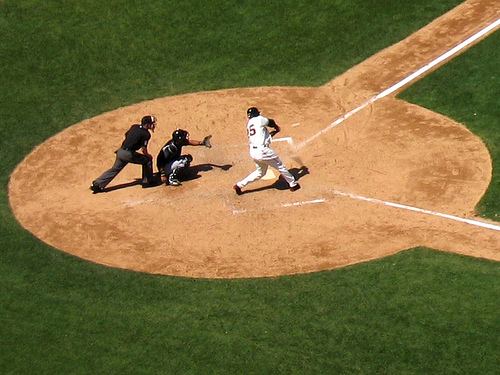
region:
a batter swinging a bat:
[233, 104, 308, 192]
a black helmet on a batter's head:
[243, 105, 260, 116]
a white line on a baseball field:
[337, 186, 498, 233]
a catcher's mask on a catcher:
[176, 127, 191, 145]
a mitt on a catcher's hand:
[203, 131, 214, 152]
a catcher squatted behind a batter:
[156, 126, 213, 187]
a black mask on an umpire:
[144, 112, 159, 129]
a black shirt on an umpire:
[120, 123, 155, 149]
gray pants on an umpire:
[93, 149, 154, 189]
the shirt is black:
[104, 119, 154, 155]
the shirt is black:
[114, 122, 147, 158]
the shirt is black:
[117, 115, 158, 159]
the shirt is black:
[111, 120, 146, 150]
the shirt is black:
[110, 121, 161, 168]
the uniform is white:
[225, 107, 304, 213]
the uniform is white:
[228, 121, 285, 203]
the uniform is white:
[230, 115, 298, 195]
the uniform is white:
[241, 107, 284, 204]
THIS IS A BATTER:
[218, 92, 309, 198]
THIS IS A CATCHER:
[155, 120, 216, 188]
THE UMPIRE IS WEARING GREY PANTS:
[68, 110, 168, 200]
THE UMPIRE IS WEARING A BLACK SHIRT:
[70, 107, 161, 195]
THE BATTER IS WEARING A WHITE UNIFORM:
[227, 98, 299, 194]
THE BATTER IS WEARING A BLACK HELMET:
[235, 102, 265, 122]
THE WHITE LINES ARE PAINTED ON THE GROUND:
[210, 10, 495, 245]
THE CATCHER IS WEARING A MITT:
[196, 131, 212, 151]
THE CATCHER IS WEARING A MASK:
[178, 124, 195, 154]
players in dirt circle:
[70, 90, 310, 229]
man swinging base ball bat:
[239, 101, 291, 192]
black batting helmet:
[243, 105, 266, 118]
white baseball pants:
[243, 148, 293, 188]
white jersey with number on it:
[241, 112, 266, 152]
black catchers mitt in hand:
[198, 133, 215, 151]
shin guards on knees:
[166, 153, 201, 178]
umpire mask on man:
[144, 114, 161, 129]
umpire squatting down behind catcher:
[88, 110, 163, 200]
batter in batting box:
[222, 94, 302, 201]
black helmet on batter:
[237, 105, 262, 122]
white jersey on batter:
[238, 116, 280, 147]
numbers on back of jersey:
[237, 118, 259, 141]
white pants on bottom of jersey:
[238, 150, 302, 185]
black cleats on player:
[287, 180, 302, 190]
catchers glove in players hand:
[198, 135, 214, 156]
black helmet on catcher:
[172, 125, 189, 142]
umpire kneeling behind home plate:
[85, 103, 161, 205]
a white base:
[258, 165, 277, 177]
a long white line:
[290, 9, 498, 159]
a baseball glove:
[200, 133, 219, 148]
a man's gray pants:
[93, 146, 156, 186]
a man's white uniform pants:
[237, 150, 297, 188]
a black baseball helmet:
[245, 100, 260, 115]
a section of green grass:
[1, 0, 442, 169]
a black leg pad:
[181, 157, 194, 168]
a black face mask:
[180, 126, 192, 147]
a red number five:
[247, 125, 256, 137]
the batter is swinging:
[233, 107, 301, 195]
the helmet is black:
[248, 107, 259, 119]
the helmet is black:
[172, 129, 188, 145]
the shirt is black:
[124, 123, 151, 151]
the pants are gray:
[95, 149, 152, 190]